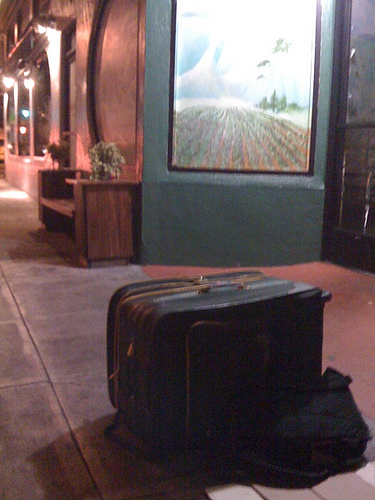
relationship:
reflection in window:
[17, 106, 31, 141] [15, 71, 35, 153]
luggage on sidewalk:
[96, 260, 371, 494] [0, 173, 212, 499]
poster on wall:
[163, 0, 324, 180] [141, 0, 326, 271]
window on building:
[15, 71, 35, 153] [0, 0, 374, 278]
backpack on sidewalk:
[188, 362, 371, 491] [0, 173, 212, 499]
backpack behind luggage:
[188, 362, 371, 491] [96, 260, 371, 494]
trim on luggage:
[102, 267, 269, 435] [96, 260, 371, 494]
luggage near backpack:
[96, 260, 371, 494] [188, 362, 371, 491]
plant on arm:
[83, 138, 130, 185] [69, 173, 143, 270]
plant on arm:
[39, 128, 77, 173] [33, 160, 86, 231]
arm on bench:
[69, 173, 143, 270] [35, 151, 149, 269]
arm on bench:
[33, 160, 86, 231] [35, 151, 149, 269]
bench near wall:
[35, 151, 149, 269] [1, 0, 143, 204]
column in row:
[45, 25, 68, 170] [0, 27, 67, 178]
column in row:
[27, 82, 35, 154] [0, 27, 67, 178]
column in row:
[10, 82, 18, 161] [0, 27, 67, 178]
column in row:
[2, 89, 12, 157] [0, 27, 67, 178]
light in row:
[21, 72, 37, 95] [0, 27, 67, 178]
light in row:
[1, 69, 19, 96] [0, 27, 67, 178]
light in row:
[43, 26, 68, 51] [0, 27, 67, 178]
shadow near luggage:
[26, 406, 208, 498] [96, 260, 371, 494]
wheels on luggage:
[315, 283, 333, 308] [96, 260, 371, 494]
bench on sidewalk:
[35, 151, 149, 269] [0, 173, 212, 499]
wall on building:
[141, 0, 326, 271] [0, 0, 374, 278]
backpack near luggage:
[188, 362, 371, 491] [96, 260, 371, 494]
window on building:
[30, 55, 54, 155] [0, 0, 374, 278]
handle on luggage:
[193, 275, 253, 300] [96, 260, 371, 494]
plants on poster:
[174, 102, 308, 172] [163, 0, 324, 180]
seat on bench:
[38, 192, 80, 218] [35, 151, 149, 269]